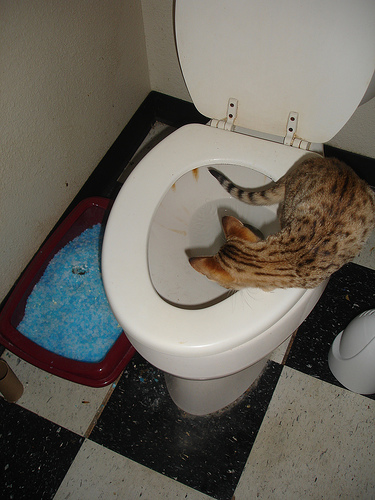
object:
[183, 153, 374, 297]
cat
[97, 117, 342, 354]
seat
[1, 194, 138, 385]
box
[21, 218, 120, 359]
sand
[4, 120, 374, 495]
linoleum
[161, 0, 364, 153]
lid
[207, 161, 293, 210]
tail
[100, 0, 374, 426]
toilet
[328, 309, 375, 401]
brush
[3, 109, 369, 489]
floor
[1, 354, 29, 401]
roll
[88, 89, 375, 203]
molding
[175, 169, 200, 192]
stain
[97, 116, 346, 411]
bowl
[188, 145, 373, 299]
animal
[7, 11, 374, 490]
photo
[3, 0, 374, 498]
room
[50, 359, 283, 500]
tile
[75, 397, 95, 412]
spot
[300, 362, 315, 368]
spot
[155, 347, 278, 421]
base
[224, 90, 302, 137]
screws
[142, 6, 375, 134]
end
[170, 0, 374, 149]
wall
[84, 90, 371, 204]
edge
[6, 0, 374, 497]
bathroom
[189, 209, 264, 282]
head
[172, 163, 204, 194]
rust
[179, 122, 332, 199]
rear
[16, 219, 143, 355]
liter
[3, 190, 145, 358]
container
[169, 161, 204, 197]
stains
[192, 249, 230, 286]
ear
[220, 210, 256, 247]
ear